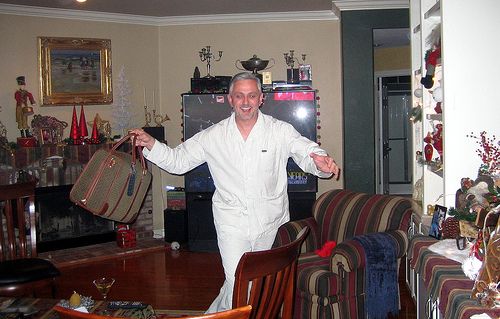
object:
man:
[127, 72, 342, 315]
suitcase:
[69, 133, 152, 224]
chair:
[231, 231, 311, 319]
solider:
[14, 76, 36, 138]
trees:
[91, 118, 101, 144]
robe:
[142, 108, 333, 315]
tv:
[180, 90, 318, 253]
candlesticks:
[198, 45, 223, 79]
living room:
[0, 0, 500, 318]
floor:
[0, 248, 226, 312]